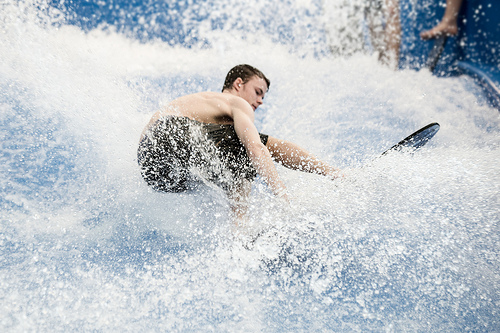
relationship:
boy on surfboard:
[138, 57, 319, 185] [262, 112, 433, 169]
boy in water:
[138, 57, 319, 185] [2, 1, 490, 332]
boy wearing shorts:
[138, 57, 319, 185] [146, 120, 250, 194]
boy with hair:
[138, 57, 319, 185] [225, 65, 273, 84]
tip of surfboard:
[394, 122, 437, 153] [262, 112, 433, 169]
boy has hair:
[138, 57, 319, 185] [225, 65, 273, 84]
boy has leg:
[138, 57, 319, 185] [258, 135, 336, 178]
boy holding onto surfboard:
[138, 57, 319, 185] [262, 112, 433, 169]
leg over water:
[433, 4, 466, 38] [2, 1, 490, 332]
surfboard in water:
[262, 112, 433, 169] [2, 1, 490, 332]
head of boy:
[222, 65, 274, 106] [138, 57, 319, 185]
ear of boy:
[236, 77, 245, 90] [138, 57, 319, 185]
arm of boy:
[223, 96, 298, 192] [138, 57, 319, 185]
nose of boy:
[259, 94, 267, 103] [138, 57, 319, 185]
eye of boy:
[255, 87, 262, 94] [138, 57, 319, 185]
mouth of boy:
[255, 105, 261, 112] [138, 57, 319, 185]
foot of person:
[416, 18, 462, 41] [385, 0, 486, 59]